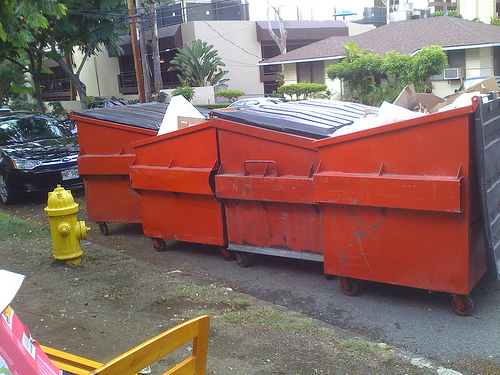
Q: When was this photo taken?
A: During the day.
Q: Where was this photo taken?
A: Outside on the street.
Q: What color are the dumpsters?
A: Orange.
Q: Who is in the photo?
A: No one.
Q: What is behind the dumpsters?
A: A car.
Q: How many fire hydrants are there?
A: 1.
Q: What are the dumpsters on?
A: The street.